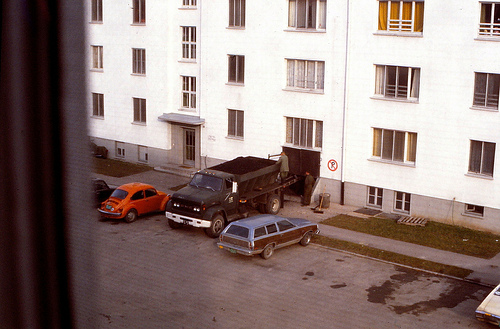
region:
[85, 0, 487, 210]
the building is white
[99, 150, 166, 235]
the car is red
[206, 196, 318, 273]
car is blue and brown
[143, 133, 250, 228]
the truck is black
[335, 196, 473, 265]
grass in front of building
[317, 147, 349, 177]
red and white sign on building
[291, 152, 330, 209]
man standing in front of entrance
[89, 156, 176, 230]
the car is a beatle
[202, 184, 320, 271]
car is a station wagon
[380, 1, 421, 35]
curtains in window are orange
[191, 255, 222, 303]
part of a floor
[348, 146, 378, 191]
part of a wall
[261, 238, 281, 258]
part of a wheel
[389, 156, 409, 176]
part of a window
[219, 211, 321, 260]
Old wagon next to huge black truck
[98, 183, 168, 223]
Orange VW bug next to huge black truck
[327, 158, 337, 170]
No parking sign in front of wagon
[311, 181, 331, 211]
Broom leaning on barrel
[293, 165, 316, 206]
Man standing near broom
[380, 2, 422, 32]
Orange curtains over window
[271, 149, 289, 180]
Man on top of black truck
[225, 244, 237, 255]
Green license plate on wagon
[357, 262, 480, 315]
Large dirt mark on street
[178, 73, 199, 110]
Window above entrance door of building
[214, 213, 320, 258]
a blue station wagon automobile with brown side panels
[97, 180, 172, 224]
an orange Volkswagen parked in front of the building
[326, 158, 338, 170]
no parking sign on the building's exterior wall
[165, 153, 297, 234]
a black truck parked in front of the delivery entrance of the building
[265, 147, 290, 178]
a man standing on the back of the delivery truck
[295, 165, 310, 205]
a man standing on the side of the truck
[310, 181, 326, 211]
a wooden outdoor broom propped on a trashcan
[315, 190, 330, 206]
a trashcan beside the delivery entrance way of the building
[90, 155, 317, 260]
automobiles parked in front of a white building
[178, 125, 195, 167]
a door on the back of the building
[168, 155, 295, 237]
large black truck in front of building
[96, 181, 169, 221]
orange car parked next to truck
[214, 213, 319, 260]
blue and brown car parked next to truck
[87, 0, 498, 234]
a large, white building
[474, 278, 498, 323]
back of a car parked to the right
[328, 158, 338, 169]
no parking sign on wall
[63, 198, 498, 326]
a paved parking lot in front of the building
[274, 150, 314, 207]
two men unloading the truck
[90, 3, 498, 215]
windows on the white building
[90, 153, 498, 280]
a small, grassy area in front of the building